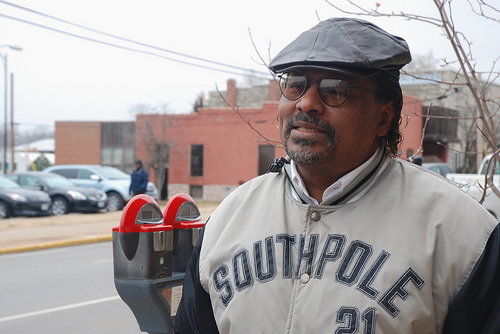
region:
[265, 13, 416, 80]
the hat is black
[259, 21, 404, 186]
the man is black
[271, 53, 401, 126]
the man has glasses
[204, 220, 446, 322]
the letters are blue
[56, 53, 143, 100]
the sky is white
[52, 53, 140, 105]
the sky is clear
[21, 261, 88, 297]
the street is gray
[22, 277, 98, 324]
the line is white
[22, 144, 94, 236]
the cars are parked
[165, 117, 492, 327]
the jacket is gray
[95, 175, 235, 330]
Two parking meters.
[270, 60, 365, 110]
The man is wearing sunglasses.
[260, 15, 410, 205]
The man is wearing a dark colored hat.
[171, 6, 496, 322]
The man is wearing a gray and black jacket.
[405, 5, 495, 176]
A tree branch that has no leaves on it.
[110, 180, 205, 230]
The top of the parking meters is red.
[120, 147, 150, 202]
A person is walking down the sidewalk.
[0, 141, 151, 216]
Three vehicles are parked.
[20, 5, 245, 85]
Two power lines.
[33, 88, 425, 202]
A large brick building.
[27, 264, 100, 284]
the street is gray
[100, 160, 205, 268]
the meter is red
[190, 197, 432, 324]
the words are blue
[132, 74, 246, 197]
the building is red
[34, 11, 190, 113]
the sky is white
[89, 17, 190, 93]
the sky is clear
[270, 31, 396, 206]
the man has glasses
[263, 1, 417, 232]
the man has a hat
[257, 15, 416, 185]
the man is smiling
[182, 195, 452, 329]
the jacket says southpole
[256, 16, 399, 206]
a man with a hat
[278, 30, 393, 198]
a man with facial hair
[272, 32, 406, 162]
a man with glasses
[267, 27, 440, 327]
a man with a white and blue jacket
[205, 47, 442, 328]
a man with a south pole jacket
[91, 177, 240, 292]
red and black parking meters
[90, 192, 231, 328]
black and red parking meteres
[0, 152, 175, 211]
three vehicles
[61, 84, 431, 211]
a brick building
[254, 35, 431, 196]
a man with facial hair and glasses